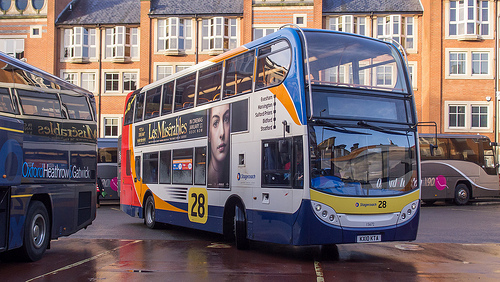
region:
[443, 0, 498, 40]
white window in tan building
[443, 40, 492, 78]
white window in tan building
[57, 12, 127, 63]
white window in tan building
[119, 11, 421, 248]
blue and white bus pulling into parking space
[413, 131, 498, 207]
two tone gray bus in the parking lot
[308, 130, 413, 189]
reflection on the windshield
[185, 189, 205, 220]
black numbers on yellow background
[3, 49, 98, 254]
blue double decker bus in the parking lot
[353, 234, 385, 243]
white license plate with black lettering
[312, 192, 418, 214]
yellow stripe on front of bus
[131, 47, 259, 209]
this is public transit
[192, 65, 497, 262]
the bus is blue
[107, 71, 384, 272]
the bus is white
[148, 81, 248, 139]
the bus has windows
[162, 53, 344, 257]
the bus is a double decker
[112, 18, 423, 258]
this is a bus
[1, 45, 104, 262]
this is a bus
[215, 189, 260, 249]
this is a tyre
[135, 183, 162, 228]
this is a tyre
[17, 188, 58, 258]
this is a tyre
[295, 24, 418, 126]
this is a mirror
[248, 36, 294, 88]
this is a mirror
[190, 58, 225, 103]
this is a mirror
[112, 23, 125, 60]
this is a mirror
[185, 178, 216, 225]
this is a number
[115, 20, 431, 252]
a double level bus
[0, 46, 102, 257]
a parked bus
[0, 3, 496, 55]
a red building with several windows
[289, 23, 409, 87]
a large window on a bus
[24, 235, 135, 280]
a white line painted on pavement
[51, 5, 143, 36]
a building with a shingled roof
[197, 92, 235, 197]
a picture on a the side of a bus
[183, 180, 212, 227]
a black number painted on the side of a bus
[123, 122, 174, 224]
red and yellow stripe on a bus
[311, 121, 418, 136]
windshield wipers on a bus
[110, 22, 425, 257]
large blue red and white bus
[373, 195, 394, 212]
black bus number 28 on front of bus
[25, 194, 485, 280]
wet parking lot with two buses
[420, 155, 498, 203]
grey windowless car parked in lot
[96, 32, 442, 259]
The bus is turning on the street.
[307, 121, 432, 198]
The bus has a large windshield.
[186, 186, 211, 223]
The number of the bus is written in black with a yellow back.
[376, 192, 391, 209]
The number of the bus is on the front of the bus.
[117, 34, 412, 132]
The bus has a upper deck.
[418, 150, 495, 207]
A car is parked on the side of the bus,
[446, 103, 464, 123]
glass window on the building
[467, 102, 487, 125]
glass window on the building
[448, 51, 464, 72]
glass window on the building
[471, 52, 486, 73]
glass window on the building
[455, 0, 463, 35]
glass window on the building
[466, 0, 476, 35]
glass window on the building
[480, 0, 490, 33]
glass window on the building